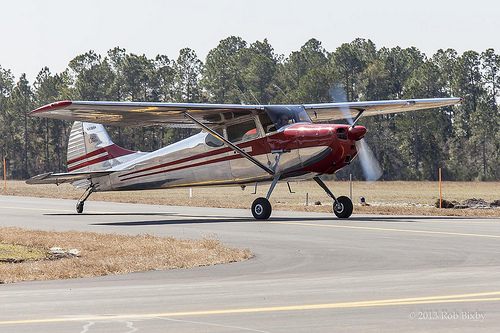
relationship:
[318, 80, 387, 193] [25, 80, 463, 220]
propeller in front of airport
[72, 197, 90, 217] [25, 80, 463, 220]
tire on airport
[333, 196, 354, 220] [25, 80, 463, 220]
front on airport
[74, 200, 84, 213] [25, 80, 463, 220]
back on airport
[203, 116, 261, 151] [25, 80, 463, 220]
window on airport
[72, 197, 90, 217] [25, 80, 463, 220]
tire in rear of airport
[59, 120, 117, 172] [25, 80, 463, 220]
tail wing on airport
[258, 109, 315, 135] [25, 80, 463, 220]
window on front of airport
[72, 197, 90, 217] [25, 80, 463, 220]
tire on back of airport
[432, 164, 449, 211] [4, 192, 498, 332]
post on runway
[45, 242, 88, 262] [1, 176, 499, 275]
stone in grass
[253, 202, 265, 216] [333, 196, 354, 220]
trim in front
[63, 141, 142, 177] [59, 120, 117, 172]
stripe on tail wing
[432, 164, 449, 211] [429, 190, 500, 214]
post in ground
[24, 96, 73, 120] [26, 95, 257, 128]
red edge on wing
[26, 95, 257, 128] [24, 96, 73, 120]
wing has red edge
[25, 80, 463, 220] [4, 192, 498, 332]
airport on runway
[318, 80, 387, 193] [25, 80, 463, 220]
propeller on airport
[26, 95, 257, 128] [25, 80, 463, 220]
wing on airport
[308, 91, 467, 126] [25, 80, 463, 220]
wing on airport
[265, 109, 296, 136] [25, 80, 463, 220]
pilot of airport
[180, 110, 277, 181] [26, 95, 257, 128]
beam supports wing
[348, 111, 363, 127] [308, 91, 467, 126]
beam supports wing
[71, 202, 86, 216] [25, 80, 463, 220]
landing gear on airport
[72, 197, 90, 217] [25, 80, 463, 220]
tire on rear of airport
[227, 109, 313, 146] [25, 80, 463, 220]
cockpit in airport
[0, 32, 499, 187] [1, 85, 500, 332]
trees near airport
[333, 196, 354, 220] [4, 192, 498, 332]
front on runway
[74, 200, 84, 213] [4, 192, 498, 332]
back on runway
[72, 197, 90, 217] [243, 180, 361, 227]
tire in front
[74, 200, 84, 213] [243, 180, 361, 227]
back in front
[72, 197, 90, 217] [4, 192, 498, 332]
tire on runway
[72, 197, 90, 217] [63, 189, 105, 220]
tire in back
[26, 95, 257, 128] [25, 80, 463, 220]
wing on top of airport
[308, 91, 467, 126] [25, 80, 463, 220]
wing on top of airport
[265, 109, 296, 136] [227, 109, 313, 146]
pilot in cockpit